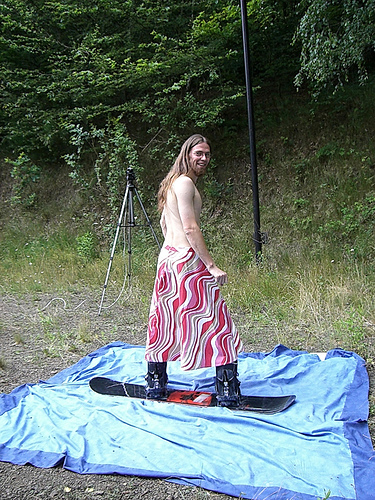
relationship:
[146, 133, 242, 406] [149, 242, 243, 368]
man wearing skirt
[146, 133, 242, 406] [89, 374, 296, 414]
man strapped on snowboard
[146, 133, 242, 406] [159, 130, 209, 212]
man has hair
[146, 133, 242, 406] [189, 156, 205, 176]
man has beard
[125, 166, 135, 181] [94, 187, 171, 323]
camera on top of tripod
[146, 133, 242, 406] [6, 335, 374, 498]
man on top of tarp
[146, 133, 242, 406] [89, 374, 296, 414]
man standing on snowboard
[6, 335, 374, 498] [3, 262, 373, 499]
tarp laying on ground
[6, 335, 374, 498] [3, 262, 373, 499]
tarp on top of ground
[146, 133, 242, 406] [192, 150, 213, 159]
man has glasses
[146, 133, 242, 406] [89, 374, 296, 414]
man riding snowboard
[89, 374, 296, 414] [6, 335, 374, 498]
snowboard on top of tarp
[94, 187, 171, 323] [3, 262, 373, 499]
tripod standing on ground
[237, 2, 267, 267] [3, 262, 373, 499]
pole stuck in ground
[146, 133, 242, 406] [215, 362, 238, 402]
man has foot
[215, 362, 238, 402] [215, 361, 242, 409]
foot has snowboard boot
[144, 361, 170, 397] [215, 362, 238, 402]
snowboard boot on foot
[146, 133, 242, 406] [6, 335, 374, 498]
man using tarp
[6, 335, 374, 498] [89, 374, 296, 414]
tarp protects snowboard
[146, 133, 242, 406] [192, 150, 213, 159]
man wearing glasses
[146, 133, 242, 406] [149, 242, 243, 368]
man wears skirt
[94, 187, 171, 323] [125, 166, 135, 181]
tripod holding camera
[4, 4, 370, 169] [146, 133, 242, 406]
tree in front of man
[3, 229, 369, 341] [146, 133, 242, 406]
grass in front of man